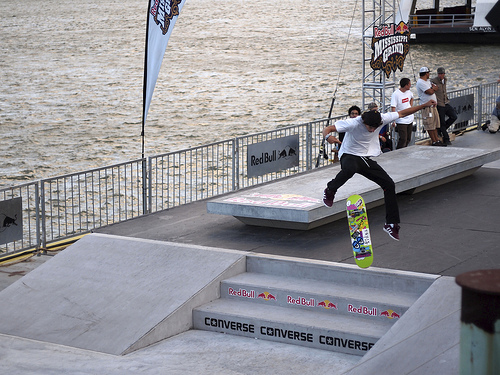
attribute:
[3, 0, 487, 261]
water — body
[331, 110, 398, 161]
t-shirt — white 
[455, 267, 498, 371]
pole — green 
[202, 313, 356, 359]
letter — black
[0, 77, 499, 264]
metal fencing — silver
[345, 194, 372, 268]
skateboard — green 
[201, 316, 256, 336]
converse — advertisement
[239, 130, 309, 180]
sign — white 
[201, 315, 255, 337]
letter — black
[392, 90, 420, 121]
shirt — white 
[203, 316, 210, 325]
letter — black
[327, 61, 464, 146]
group — friends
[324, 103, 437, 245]
man — flying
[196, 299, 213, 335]
letter — black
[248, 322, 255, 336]
letter — black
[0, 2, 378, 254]
ocean — calm, water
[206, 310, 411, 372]
step — concrete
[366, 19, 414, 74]
sign — black 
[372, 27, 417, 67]
mississippi grand — skateboarding tournament